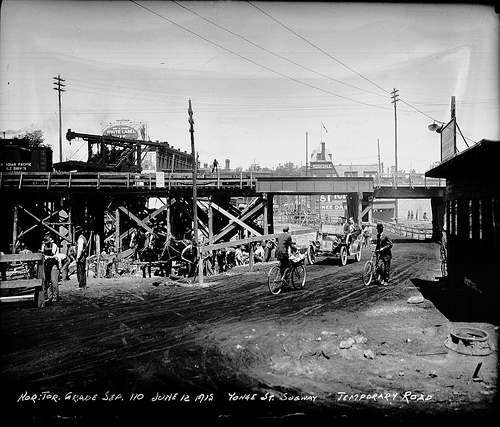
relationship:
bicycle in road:
[267, 254, 309, 297] [5, 218, 497, 423]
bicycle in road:
[360, 249, 390, 285] [5, 218, 497, 423]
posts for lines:
[388, 82, 399, 176] [2, 2, 477, 132]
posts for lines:
[49, 72, 67, 167] [2, 2, 477, 132]